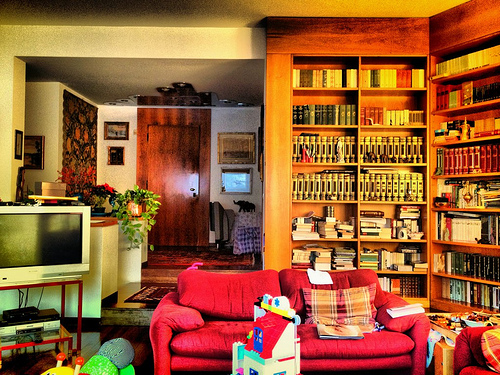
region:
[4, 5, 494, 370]
foyer and living room in cluttered home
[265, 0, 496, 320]
rows of shelves in wooden bookcases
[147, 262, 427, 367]
red sofa lined with flat cushions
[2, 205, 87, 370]
white television set on metal stand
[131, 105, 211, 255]
wooden door in matching wooden frame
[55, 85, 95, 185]
artwork of red flowers on black background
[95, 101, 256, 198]
framed pictures on sides walls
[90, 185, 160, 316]
hanging plant on one of two counters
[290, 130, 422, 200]
set of reference books on shelves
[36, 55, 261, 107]
oval mirrored panels on ceiling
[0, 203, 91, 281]
the TV on the stand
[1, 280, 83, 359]
the stand under the TV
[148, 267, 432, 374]
the sofa in the room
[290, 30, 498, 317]
the large book shelves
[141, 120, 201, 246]
a wooden door in the room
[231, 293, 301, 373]
the toy in front of the sofa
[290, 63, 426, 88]
the books on the top shelf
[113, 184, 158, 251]
the green plant on the counter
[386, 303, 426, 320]
a book on the arm of the chair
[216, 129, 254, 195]
pictures hanging on the wall near the door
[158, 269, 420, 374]
red love seat in living room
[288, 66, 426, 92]
books on top shelf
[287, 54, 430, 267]
shelves of wood bookcase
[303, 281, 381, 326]
red and yellow plaid pillow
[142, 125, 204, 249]
closed shiny wood door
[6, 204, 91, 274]
television with gray border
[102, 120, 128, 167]
framed pictures on wall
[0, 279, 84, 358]
table with red legs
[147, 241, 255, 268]
rug with print on floor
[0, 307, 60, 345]
electronics on glass table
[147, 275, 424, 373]
a red couch with a pillow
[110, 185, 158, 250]
a plant growing down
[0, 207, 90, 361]
TV on a stand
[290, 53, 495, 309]
a large amount of books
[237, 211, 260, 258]
a plaid table cloth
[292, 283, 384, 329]
the pillow is plaid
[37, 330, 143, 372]
a worm ride on toy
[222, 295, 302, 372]
a childs play house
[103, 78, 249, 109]
decorative mirrored ceiling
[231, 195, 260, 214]
an elephant on a table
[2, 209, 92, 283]
small television that is not on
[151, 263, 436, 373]
plush red microfiber loveseat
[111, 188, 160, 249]
potted plant of ivy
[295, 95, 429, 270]
bookshelves full of books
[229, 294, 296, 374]
child's toy made of plastic blocks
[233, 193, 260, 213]
small figurine of an elephant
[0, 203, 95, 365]
TV stand holding a television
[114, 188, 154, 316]
pillar with a potted plant in it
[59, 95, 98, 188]
large decorative wall art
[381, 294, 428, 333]
book laying on the red arm of a loveseat